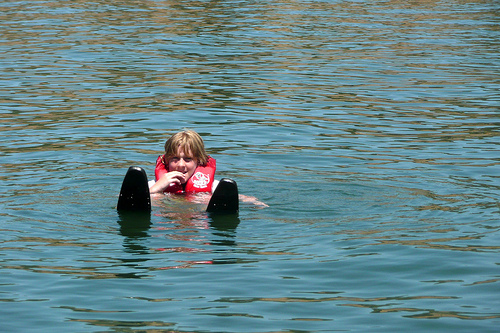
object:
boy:
[148, 129, 270, 208]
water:
[0, 0, 500, 333]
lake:
[0, 0, 500, 333]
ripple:
[236, 106, 437, 160]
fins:
[116, 166, 152, 215]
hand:
[156, 170, 187, 192]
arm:
[145, 185, 155, 195]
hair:
[161, 128, 210, 168]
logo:
[190, 171, 210, 188]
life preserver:
[154, 153, 217, 200]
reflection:
[114, 236, 326, 281]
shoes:
[204, 177, 241, 213]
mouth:
[179, 170, 189, 176]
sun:
[168, 18, 382, 68]